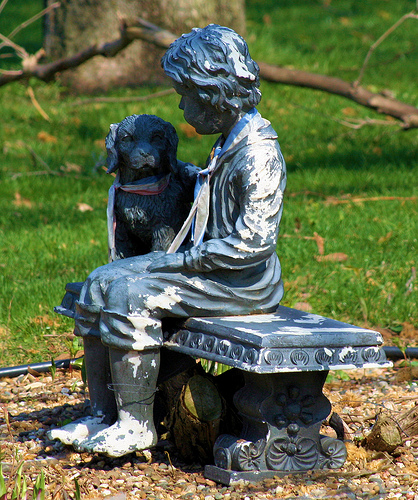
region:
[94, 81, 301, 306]
statue is grey in color.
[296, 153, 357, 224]
grass is green in color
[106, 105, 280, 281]
statue of girl and dog sitting in the bench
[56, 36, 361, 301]
daytime picture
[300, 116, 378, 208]
shadow is in ground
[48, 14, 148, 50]
woods are brown in color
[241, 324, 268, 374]
bench is grey in color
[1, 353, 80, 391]
tube is black in color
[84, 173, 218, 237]
white color cloth is tied around the neck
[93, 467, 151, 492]
pebbles are under the girl legs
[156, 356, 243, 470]
tree stump under statue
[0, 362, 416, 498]
gravel bed with weeds growing in it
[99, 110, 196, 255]
statue dog sitting next to statue girl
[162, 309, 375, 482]
ornate bench that statue girl and dog are sitting on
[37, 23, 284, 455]
a statue of a young girl sitting on a bench and petting a dog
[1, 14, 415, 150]
fallen tree branch lying in the grass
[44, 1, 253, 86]
trunk of a large tree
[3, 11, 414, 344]
large grassy area behind statue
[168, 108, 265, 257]
ribbons tied around statues neck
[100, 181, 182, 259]
ribbons tied around dogs neck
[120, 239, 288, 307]
the statue is made of stone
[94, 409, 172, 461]
white patches on the foot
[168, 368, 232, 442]
the tree trunk is brown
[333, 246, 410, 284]
the grass is green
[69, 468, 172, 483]
the stones are brown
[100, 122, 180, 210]
the dog is made of stone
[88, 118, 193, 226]
the dog is grey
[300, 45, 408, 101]
the branch has fallen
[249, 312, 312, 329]
the bench has white patches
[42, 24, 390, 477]
statue of boy and dog sitting on bench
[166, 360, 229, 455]
wood log under bench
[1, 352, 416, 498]
brown and white rocks surround bench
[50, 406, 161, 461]
paint on statues feet is chipping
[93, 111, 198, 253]
someone tied a collar on the dog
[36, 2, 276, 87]
large tree behind the statue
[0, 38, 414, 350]
green grass around statue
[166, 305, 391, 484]
bench is ornately decorated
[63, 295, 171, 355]
boys pants are rolled up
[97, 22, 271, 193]
boy is looking at dog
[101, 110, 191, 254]
the dog is gray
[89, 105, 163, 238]
dog is made of stone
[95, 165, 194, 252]
the dog has collar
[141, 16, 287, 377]
the boy is sitting on a bench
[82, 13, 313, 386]
the boy is made of stone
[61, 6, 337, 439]
the boy is looking at the dog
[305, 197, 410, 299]
the grass is green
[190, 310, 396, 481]
the bench is gray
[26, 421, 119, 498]
the ground has stones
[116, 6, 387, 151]
the tree branch is brown